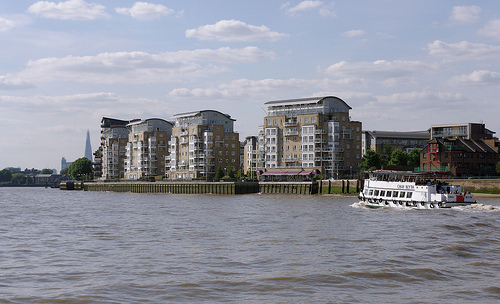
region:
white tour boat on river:
[351, 167, 477, 210]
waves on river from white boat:
[455, 201, 493, 216]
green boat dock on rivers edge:
[256, 180, 315, 197]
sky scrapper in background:
[83, 125, 93, 175]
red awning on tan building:
[259, 169, 316, 179]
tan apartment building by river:
[259, 94, 364, 176]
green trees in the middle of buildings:
[361, 147, 424, 176]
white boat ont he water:
[358, 167, 459, 211]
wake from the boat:
[455, 198, 497, 218]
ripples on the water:
[7, 189, 491, 299]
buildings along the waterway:
[100, 98, 487, 178]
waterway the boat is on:
[5, 185, 498, 300]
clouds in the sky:
[6, 1, 497, 117]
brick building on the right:
[414, 117, 494, 175]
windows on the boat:
[358, 187, 422, 208]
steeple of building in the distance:
[78, 129, 95, 165]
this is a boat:
[342, 149, 489, 256]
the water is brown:
[23, 138, 328, 303]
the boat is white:
[348, 153, 485, 245]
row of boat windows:
[359, 171, 419, 205]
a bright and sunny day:
[31, 12, 485, 302]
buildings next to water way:
[69, 65, 385, 210]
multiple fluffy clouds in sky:
[29, 11, 485, 128]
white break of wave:
[411, 190, 498, 225]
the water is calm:
[25, 177, 291, 302]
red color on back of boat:
[453, 190, 465, 203]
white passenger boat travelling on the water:
[351, 158, 493, 218]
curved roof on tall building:
[273, 86, 351, 111]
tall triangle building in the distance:
[79, 123, 94, 160]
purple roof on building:
[261, 161, 321, 178]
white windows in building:
[254, 120, 288, 170]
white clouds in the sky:
[139, 26, 252, 87]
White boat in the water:
[350, 154, 482, 228]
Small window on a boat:
[360, 184, 369, 196]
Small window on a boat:
[365, 185, 373, 200]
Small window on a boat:
[373, 184, 378, 199]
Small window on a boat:
[379, 185, 385, 202]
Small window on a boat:
[383, 185, 391, 202]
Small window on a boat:
[390, 185, 399, 201]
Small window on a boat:
[397, 185, 404, 199]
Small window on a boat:
[403, 191, 414, 201]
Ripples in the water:
[3, 178, 493, 298]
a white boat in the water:
[349, 174, 486, 219]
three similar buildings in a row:
[117, 98, 362, 185]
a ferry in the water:
[353, 165, 483, 211]